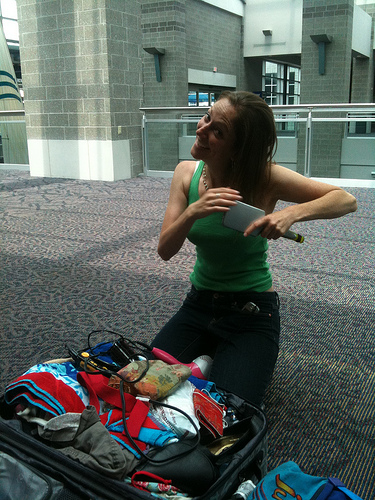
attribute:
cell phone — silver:
[240, 299, 263, 313]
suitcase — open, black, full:
[1, 346, 266, 496]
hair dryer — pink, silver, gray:
[152, 345, 212, 379]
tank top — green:
[185, 156, 273, 290]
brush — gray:
[223, 201, 306, 243]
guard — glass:
[144, 117, 373, 179]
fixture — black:
[311, 31, 334, 75]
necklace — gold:
[199, 166, 215, 197]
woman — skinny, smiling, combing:
[155, 91, 358, 393]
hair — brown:
[221, 90, 279, 191]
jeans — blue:
[152, 288, 282, 396]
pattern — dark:
[2, 65, 19, 80]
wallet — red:
[193, 390, 224, 439]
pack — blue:
[255, 459, 359, 499]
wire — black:
[76, 331, 201, 460]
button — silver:
[212, 289, 222, 299]